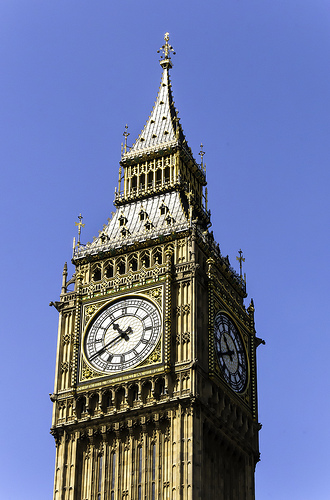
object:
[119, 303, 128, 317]
numeral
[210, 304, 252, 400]
clock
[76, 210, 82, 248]
ornamental pole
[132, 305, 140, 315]
roman numeral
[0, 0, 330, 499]
sky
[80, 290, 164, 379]
clock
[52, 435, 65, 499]
tower edge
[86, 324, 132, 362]
hands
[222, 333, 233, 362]
hands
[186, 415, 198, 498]
edge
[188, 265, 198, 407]
edge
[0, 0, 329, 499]
close shot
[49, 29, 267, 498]
building